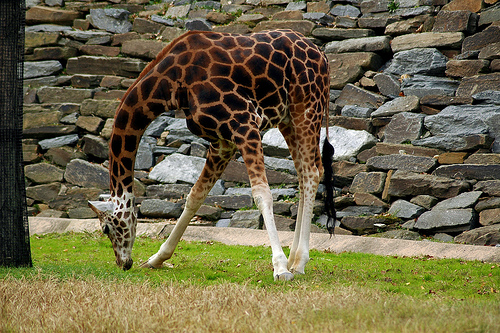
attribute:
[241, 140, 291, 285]
legs — spread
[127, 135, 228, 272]
legs — spread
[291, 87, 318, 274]
legs — spread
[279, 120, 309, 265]
legs — spread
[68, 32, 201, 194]
neck — long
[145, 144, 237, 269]
leg — white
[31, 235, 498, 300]
grass — mowed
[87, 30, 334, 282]
giraffe — bent over, grazing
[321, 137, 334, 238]
hair — black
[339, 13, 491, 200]
wall — rock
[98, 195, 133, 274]
head — white, brown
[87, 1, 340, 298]
giraffe — red, brown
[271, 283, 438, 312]
grass — green 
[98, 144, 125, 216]
mane — red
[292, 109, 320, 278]
leg — back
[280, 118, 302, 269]
leg — back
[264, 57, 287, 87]
spot — brown 